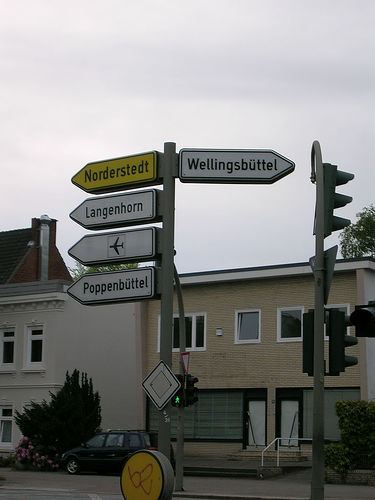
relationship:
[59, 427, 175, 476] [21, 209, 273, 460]
car by building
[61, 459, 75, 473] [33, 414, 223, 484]
wheels on car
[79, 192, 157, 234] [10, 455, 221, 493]
sign by road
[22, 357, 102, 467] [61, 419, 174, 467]
tree by car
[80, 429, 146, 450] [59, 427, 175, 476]
windows on car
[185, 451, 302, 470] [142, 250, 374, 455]
sidewalk in front of building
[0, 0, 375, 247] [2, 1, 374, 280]
clouds in sky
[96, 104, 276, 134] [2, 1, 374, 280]
clouds in sky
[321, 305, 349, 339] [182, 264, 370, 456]
window of building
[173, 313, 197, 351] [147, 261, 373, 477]
window of building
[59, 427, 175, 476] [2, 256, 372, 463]
car parked in front of building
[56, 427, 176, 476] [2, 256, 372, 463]
car in front of building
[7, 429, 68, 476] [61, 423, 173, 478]
purple flowers in front of car